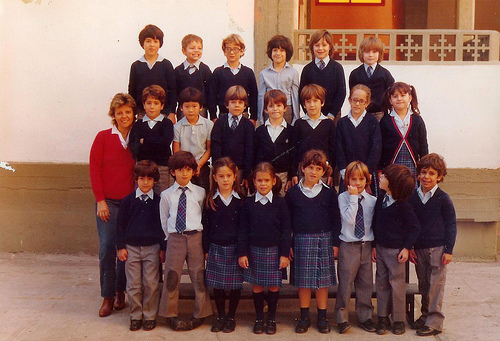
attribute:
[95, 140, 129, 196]
shirt — red, long sleeved, white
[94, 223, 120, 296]
jeans — blue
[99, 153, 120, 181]
sweater — red, blue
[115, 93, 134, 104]
hair — blonde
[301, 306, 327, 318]
socks — black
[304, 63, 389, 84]
sweaters — navy blue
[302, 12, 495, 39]
fence — decorative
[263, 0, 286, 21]
wall — brown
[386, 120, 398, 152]
sweater — blue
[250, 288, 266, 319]
sock — black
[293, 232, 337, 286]
skirt — plaid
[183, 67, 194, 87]
neck tie — long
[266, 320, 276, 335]
shoe — black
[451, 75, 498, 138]
wall — white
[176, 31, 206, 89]
boy — blonde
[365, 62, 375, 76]
tie — blue patterened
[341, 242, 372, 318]
pants — khaki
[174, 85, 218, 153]
boy — asian